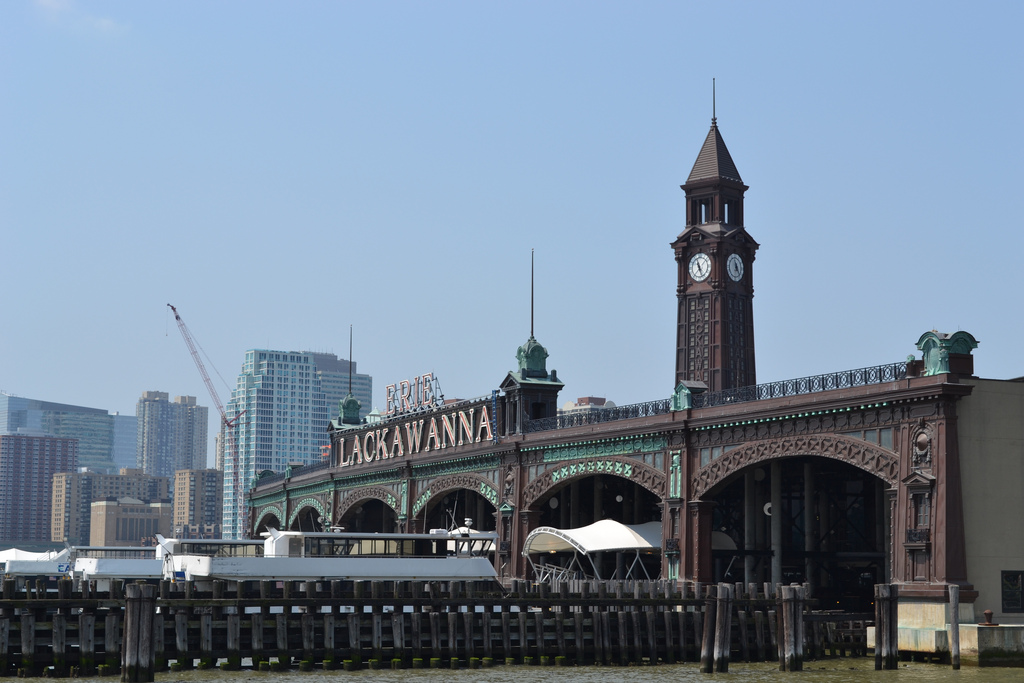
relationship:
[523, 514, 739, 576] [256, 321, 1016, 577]
boat under bridge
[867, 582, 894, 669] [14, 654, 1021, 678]
posts in water